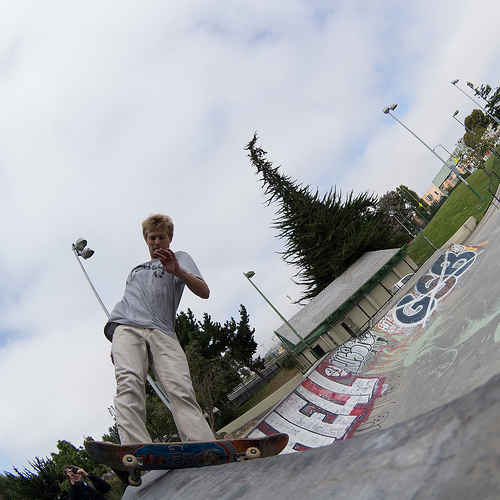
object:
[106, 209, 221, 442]
man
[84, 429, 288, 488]
skateboard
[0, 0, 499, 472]
clouds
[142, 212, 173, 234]
hair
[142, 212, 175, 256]
head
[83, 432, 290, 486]
skate board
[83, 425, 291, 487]
brown jacket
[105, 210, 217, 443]
skater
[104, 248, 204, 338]
shirt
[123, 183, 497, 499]
ramp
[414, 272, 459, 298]
letter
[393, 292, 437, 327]
letter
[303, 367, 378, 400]
letter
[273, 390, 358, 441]
letter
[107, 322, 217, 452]
pants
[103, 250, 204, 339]
tee shirt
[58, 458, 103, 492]
man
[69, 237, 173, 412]
post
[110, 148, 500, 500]
skateboard park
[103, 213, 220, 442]
skateboarder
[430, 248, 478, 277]
letter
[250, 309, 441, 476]
graffiti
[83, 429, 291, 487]
giraffe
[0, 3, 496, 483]
sky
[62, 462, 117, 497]
person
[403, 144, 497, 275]
grassy area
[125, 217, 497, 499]
ground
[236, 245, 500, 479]
skate ramp